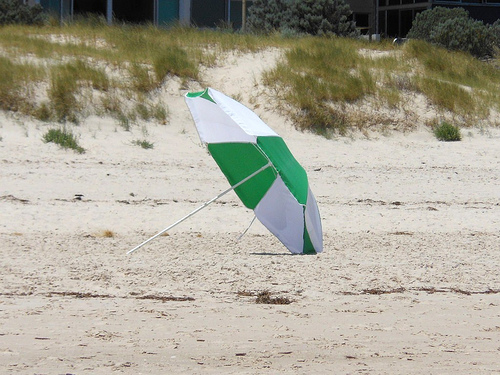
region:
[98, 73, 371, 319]
a green and white umbrella on the beach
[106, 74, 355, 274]
a green and white umbrella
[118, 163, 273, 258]
a white pole of the umbrella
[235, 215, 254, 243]
a white strap hanging from umbrella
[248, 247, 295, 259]
small shadow on ground from umbrella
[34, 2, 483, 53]
a barely visible building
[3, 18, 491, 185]
a sand hill with grass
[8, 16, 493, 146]
a sand hill with grass behind umbrella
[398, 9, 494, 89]
green shrubs up on hill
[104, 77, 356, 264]
a green and white umbella left on beach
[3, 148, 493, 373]
A white sandy beach.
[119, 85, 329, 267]
A green and white umbrella on the beach.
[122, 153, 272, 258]
A white handle on the umbrella.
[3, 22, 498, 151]
Tall sand dunes.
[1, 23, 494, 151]
Green vegetation on the sand dunes.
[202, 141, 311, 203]
Green panels on the umbrella.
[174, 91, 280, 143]
White panels on the umbrella.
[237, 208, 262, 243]
A strap the keep the umbrella closed.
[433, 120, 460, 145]
A small shrub near the dune.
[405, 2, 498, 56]
Trees at the top of the sand dunes.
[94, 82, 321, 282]
umbrella on the beach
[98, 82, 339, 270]
umbrella on the sand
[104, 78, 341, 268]
green and white umbrella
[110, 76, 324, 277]
green and white umbrella tilted over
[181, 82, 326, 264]
green and white sections of umbrella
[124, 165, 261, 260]
long white pole for umbrella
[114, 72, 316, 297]
sun umbrella in the sand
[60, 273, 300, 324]
sea weed on the sand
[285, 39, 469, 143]
plants growing on side of sand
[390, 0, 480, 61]
large bushes behind sand hill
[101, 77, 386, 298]
Umbrella on the beach.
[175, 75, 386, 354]
Green and white umbrella.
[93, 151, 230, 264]
Handle of the umbrella.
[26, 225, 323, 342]
Sand on the beach.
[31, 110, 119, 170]
Grass on the beach.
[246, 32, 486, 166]
Grass on the dunes.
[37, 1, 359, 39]
Building in the background.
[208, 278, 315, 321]
Dirt on the beach.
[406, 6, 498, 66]
bushes in the background.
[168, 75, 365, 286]
Green and white striped umbrella.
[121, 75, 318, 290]
a white and green umbrella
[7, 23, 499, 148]
grass on the hill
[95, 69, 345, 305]
an umbrella lying on the beach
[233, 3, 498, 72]
some shrubs on top of hill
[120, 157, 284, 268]
a white pole to the umbrella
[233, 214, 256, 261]
white strap hanging from umbrella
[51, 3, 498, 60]
a building is barely seen above the hill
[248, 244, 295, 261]
small shadow cast by umbrella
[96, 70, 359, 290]
an umbrella left on the beach